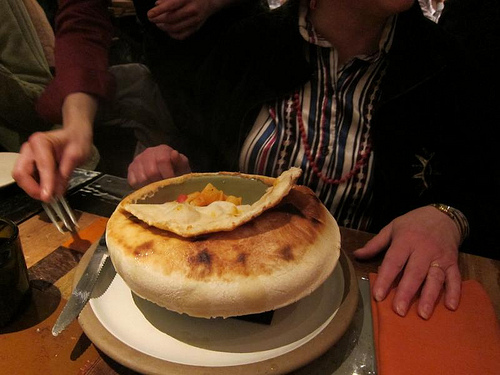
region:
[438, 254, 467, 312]
finger on person's hand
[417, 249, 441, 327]
finger on person's hand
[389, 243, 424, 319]
finger on person's hand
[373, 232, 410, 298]
finger on person's hand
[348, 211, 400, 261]
finger on person's hand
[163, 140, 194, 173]
finger on person's hand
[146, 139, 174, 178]
finger on person's hand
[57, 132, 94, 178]
finger on person's hand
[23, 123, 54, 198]
finger on person's hand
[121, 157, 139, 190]
finger on person's hand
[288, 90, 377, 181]
a red pearl necklace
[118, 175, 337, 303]
food on a plate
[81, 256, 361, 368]
a white and brown plate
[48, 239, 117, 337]
a knife on the plate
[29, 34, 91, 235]
a hand holding a fork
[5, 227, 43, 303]
a glass on the table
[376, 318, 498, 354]
the table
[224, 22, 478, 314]
a person sitting in front of the food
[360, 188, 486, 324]
the hand of the person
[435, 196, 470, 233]
the watch on the hand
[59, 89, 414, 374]
a large pot pie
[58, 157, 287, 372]
a pot pie on a plate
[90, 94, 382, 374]
a plate with a cook meal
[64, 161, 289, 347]
a plate iwth a cooke dpot pie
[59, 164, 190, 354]
a knife on a plate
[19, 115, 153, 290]
a hand holding a fork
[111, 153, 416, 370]
a pot pie open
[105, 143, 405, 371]
a plate on a table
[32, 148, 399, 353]
a table with a plate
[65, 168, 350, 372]
a table with food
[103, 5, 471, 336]
a woman about to eat a giant pie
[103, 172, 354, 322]
a giant pie of peaches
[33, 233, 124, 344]
a knife on the side of a plate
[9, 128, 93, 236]
a hand holding a fork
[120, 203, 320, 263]
a piece of crust pulled to the side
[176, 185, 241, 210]
pieces of baked peaches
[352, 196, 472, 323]
the hand of a woman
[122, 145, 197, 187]
the hand of a woman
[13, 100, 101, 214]
the hand of a woman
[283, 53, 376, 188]
a red necklace worn by a woman